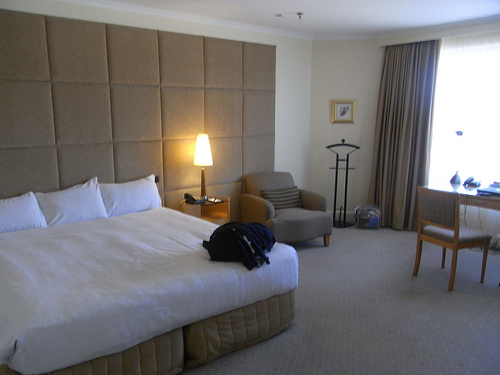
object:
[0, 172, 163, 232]
pillows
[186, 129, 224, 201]
lamp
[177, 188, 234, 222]
table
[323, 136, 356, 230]
clothes stand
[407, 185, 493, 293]
chair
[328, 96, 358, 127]
picture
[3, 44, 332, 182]
wall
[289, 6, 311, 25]
sprinkler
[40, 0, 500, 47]
ceiling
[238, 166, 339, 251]
chair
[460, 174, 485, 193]
phone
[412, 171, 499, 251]
desk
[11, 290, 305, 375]
bedskirt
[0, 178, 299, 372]
bed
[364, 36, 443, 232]
curtains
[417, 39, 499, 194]
window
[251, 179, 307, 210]
pillow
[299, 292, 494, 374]
carpet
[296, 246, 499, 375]
ground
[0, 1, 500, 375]
room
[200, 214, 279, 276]
clothes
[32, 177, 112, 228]
pillow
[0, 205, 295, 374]
blanket